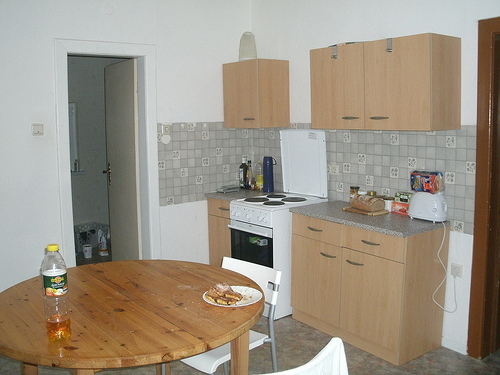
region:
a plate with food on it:
[191, 278, 270, 313]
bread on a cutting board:
[338, 186, 395, 220]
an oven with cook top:
[218, 188, 324, 262]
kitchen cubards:
[303, 36, 460, 131]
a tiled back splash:
[328, 141, 421, 175]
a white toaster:
[406, 185, 456, 227]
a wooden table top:
[80, 272, 190, 348]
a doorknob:
[98, 158, 121, 189]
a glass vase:
[229, 25, 264, 64]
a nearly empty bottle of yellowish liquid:
[27, 237, 87, 342]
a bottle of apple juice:
[28, 233, 79, 350]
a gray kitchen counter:
[288, 192, 457, 237]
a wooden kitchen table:
[3, 254, 282, 368]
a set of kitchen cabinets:
[286, 206, 454, 366]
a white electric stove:
[230, 185, 320, 328]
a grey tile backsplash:
[157, 119, 475, 231]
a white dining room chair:
[168, 248, 285, 373]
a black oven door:
[224, 216, 277, 275]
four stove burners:
[241, 187, 308, 212]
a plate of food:
[201, 280, 261, 307]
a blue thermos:
[260, 155, 270, 195]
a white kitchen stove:
[230, 190, 330, 315]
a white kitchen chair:
[160, 255, 276, 371]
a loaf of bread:
[340, 190, 390, 215]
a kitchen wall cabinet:
[216, 55, 286, 125]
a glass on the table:
[42, 292, 73, 343]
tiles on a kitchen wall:
[156, 121, 481, 236]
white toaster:
[410, 187, 450, 227]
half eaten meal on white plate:
[197, 280, 265, 312]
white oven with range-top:
[227, 184, 322, 321]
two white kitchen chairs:
[179, 254, 351, 374]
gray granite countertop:
[290, 195, 450, 237]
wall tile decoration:
[159, 120, 474, 230]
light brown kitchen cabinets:
[196, 33, 457, 368]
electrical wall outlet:
[444, 256, 469, 285]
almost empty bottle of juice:
[37, 246, 72, 337]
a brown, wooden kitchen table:
[0, 252, 265, 373]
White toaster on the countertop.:
[405, 190, 449, 223]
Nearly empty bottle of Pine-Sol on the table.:
[39, 242, 69, 340]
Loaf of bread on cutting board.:
[343, 194, 386, 211]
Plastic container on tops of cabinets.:
[240, 27, 255, 59]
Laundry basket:
[75, 220, 110, 247]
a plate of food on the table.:
[201, 280, 257, 305]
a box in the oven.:
[245, 232, 275, 247]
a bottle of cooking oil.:
[255, 161, 262, 188]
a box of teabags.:
[392, 199, 407, 215]